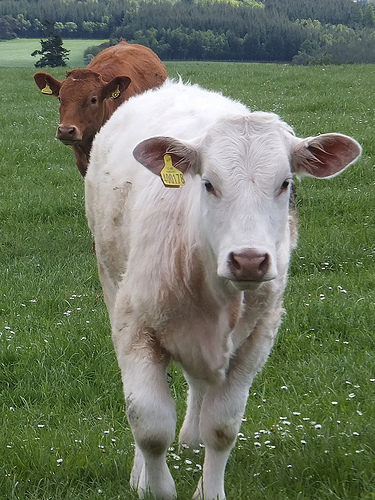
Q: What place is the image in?
A: It is at the pasture.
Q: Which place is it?
A: It is a pasture.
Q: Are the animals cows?
A: Yes, all the animals are cows.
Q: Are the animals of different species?
A: No, all the animals are cows.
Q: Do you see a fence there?
A: No, there are no fences.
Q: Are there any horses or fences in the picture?
A: No, there are no fences or horses.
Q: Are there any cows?
A: Yes, there is a cow.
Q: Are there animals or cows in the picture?
A: Yes, there is a cow.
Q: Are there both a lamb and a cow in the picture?
A: No, there is a cow but no lambs.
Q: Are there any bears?
A: No, there are no bears.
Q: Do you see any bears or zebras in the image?
A: No, there are no bears or zebras.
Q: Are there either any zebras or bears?
A: No, there are no bears or zebras.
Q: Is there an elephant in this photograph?
A: No, there are no elephants.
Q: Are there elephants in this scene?
A: No, there are no elephants.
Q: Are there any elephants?
A: No, there are no elephants.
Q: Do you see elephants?
A: No, there are no elephants.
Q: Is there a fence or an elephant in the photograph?
A: No, there are no elephants or fences.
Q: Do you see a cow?
A: Yes, there is a cow.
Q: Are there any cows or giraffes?
A: Yes, there is a cow.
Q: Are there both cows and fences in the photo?
A: No, there is a cow but no fences.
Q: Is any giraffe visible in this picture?
A: No, there are no giraffes.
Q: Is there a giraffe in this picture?
A: No, there are no giraffes.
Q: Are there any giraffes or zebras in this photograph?
A: No, there are no giraffes or zebras.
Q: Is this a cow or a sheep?
A: This is a cow.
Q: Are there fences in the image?
A: No, there are no fences.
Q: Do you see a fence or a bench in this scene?
A: No, there are no fences or benches.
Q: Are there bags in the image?
A: No, there are no bags.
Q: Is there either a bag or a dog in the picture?
A: No, there are no bags or dogs.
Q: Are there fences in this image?
A: No, there are no fences.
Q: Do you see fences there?
A: No, there are no fences.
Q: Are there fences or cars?
A: No, there are no fences or cars.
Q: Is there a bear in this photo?
A: No, there are no bears.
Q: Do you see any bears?
A: No, there are no bears.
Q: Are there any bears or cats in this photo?
A: No, there are no bears or cats.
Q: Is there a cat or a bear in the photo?
A: No, there are no bears or cats.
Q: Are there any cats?
A: No, there are no cats.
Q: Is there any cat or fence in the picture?
A: No, there are no cats or fences.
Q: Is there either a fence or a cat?
A: No, there are no cats or fences.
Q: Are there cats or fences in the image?
A: No, there are no cats or fences.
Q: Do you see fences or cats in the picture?
A: No, there are no cats or fences.